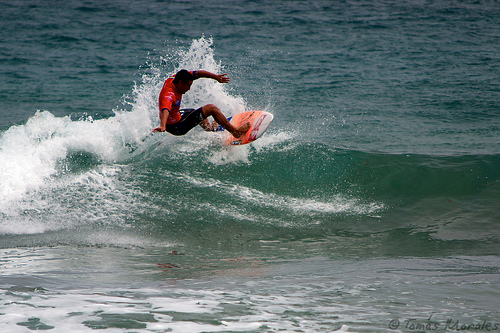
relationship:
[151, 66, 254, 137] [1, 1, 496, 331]
man surfing in ocean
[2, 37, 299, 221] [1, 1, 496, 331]
foam on ocean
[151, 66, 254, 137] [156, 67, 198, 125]
man wearing shirt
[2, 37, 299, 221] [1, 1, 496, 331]
foam crashing on ocean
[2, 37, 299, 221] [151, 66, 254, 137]
foam caused by man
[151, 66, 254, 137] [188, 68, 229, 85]
man has arm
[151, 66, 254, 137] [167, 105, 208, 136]
man wearing shorts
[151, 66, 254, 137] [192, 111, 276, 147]
man looking down at surfboard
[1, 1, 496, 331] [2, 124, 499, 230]
ocean has wave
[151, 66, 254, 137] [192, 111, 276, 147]
man on top of surfboard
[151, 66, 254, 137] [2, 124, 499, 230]
man riding wave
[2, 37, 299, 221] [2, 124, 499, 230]
foam on top of wave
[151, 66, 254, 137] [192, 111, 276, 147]
man balancing on surfboard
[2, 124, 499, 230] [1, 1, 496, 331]
wave in ocean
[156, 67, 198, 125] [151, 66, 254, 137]
shirt worn by man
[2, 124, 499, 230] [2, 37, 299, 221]
wave has foam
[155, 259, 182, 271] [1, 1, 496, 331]
seaweed floating in ocean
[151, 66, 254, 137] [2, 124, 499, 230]
man on top of wave